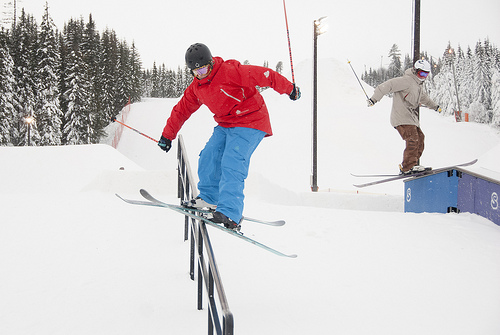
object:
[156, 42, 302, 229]
person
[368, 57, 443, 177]
person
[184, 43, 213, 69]
helmet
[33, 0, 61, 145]
tree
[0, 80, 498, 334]
snow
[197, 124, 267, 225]
pants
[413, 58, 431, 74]
helmet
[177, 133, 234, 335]
railing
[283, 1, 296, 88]
pole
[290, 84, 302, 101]
hand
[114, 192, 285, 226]
skis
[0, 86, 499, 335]
ground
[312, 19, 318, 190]
pole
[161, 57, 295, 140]
jacket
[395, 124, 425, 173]
trouser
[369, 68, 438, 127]
jacket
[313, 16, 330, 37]
light